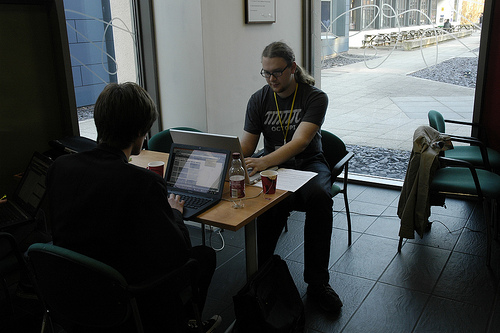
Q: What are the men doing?
A: Using computers.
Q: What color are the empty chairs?
A: Blue.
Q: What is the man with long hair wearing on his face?
A: Glasses.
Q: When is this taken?
A: During the day.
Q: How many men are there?
A: Two.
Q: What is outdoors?
A: A building.